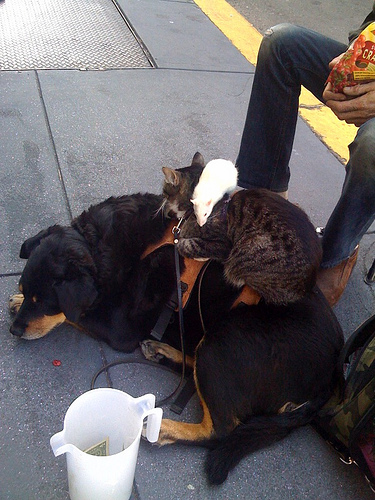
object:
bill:
[83, 434, 111, 458]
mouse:
[190, 155, 243, 226]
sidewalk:
[2, 1, 375, 497]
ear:
[51, 269, 102, 326]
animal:
[8, 189, 349, 486]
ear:
[188, 195, 198, 204]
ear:
[160, 158, 182, 189]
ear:
[190, 146, 203, 167]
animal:
[153, 141, 326, 312]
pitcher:
[50, 382, 165, 498]